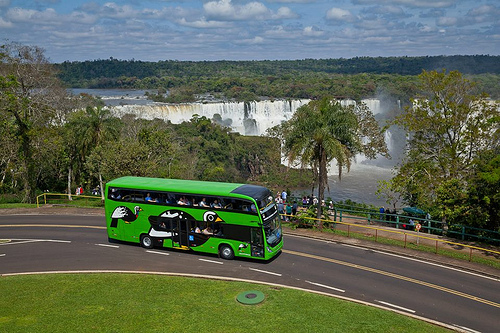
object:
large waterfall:
[43, 99, 401, 181]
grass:
[0, 270, 463, 332]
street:
[0, 208, 499, 332]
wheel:
[139, 233, 154, 248]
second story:
[103, 176, 275, 217]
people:
[283, 201, 294, 220]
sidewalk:
[281, 204, 499, 266]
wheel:
[218, 241, 234, 260]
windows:
[108, 187, 255, 216]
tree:
[266, 91, 386, 226]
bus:
[101, 176, 286, 264]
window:
[262, 213, 285, 237]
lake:
[13, 86, 499, 217]